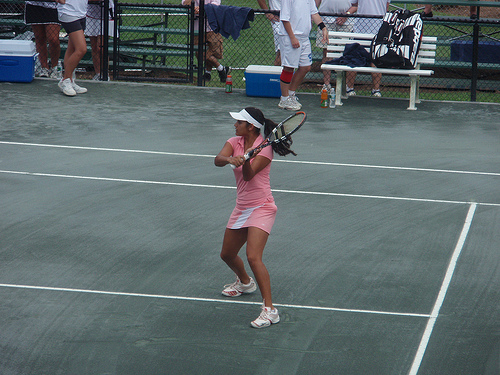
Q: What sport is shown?
A: Tennis.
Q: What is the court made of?
A: Concrete.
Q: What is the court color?
A: Gray.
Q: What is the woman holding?
A: Tennis racket.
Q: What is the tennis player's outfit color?
A: Pink.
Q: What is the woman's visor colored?
A: White.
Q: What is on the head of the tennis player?
A: Visor.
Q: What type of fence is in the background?
A: Chain link.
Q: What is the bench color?
A: White.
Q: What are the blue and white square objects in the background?
A: Coolers.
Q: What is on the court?
A: A bench.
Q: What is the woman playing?
A: Tennis.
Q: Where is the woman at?
A: A tennis court.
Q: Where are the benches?
A: Behind the woman.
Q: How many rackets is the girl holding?
A: 1.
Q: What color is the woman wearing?
A: Pink.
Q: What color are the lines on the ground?
A: White.